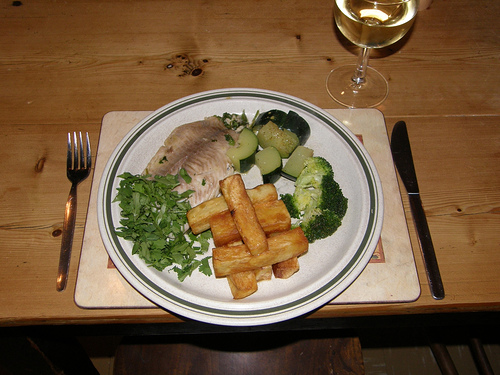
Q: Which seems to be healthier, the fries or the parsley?
A: The parsley is healthier than the fries.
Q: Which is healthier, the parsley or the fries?
A: The parsley is healthier than the fries.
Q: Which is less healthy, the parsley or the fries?
A: The fries is less healthy than the parsley.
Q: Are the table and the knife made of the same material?
A: No, the table is made of wood and the knife is made of metal.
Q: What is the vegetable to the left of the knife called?
A: The vegetable is a zucchini.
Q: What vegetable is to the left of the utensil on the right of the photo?
A: The vegetable is a zucchini.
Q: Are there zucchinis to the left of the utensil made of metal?
A: Yes, there is a zucchini to the left of the knife.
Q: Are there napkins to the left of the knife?
A: No, there is a zucchini to the left of the knife.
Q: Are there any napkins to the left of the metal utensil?
A: No, there is a zucchini to the left of the knife.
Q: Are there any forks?
A: Yes, there is a fork.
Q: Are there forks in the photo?
A: Yes, there is a fork.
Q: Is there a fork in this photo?
A: Yes, there is a fork.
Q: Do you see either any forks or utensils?
A: Yes, there is a fork.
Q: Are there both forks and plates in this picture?
A: Yes, there are both a fork and a plate.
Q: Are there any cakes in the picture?
A: No, there are no cakes.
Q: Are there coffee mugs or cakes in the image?
A: No, there are no cakes or coffee mugs.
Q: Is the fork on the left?
A: Yes, the fork is on the left of the image.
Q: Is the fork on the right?
A: No, the fork is on the left of the image.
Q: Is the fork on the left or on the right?
A: The fork is on the left of the image.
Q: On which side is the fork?
A: The fork is on the left of the image.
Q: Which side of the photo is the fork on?
A: The fork is on the left of the image.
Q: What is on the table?
A: The fork is on the table.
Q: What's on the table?
A: The fork is on the table.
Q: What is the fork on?
A: The fork is on the table.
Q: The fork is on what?
A: The fork is on the table.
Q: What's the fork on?
A: The fork is on the table.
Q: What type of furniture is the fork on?
A: The fork is on the table.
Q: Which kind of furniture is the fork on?
A: The fork is on the table.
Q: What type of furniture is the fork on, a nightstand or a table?
A: The fork is on a table.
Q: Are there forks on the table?
A: Yes, there is a fork on the table.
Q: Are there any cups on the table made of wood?
A: No, there is a fork on the table.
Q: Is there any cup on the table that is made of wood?
A: No, there is a fork on the table.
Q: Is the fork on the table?
A: Yes, the fork is on the table.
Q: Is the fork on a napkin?
A: No, the fork is on the table.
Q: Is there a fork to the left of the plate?
A: Yes, there is a fork to the left of the plate.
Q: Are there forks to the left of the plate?
A: Yes, there is a fork to the left of the plate.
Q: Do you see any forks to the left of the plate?
A: Yes, there is a fork to the left of the plate.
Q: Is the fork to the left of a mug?
A: No, the fork is to the left of the plate.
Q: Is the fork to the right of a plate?
A: No, the fork is to the left of a plate.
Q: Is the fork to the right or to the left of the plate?
A: The fork is to the left of the plate.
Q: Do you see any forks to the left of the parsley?
A: Yes, there is a fork to the left of the parsley.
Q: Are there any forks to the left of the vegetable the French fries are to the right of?
A: Yes, there is a fork to the left of the parsley.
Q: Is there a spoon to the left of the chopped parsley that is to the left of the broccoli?
A: No, there is a fork to the left of the parsley.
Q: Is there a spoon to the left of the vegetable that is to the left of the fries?
A: No, there is a fork to the left of the parsley.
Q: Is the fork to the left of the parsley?
A: Yes, the fork is to the left of the parsley.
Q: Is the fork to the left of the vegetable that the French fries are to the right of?
A: Yes, the fork is to the left of the parsley.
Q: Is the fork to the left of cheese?
A: No, the fork is to the left of the parsley.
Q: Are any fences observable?
A: No, there are no fences.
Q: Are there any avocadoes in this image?
A: No, there are no avocadoes.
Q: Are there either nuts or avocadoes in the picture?
A: No, there are no avocadoes or nuts.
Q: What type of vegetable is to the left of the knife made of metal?
A: The vegetable is a zucchini.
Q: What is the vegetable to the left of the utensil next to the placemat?
A: The vegetable is a zucchini.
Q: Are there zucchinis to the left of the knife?
A: Yes, there is a zucchini to the left of the knife.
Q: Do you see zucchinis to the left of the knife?
A: Yes, there is a zucchini to the left of the knife.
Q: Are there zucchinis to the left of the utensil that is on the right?
A: Yes, there is a zucchini to the left of the knife.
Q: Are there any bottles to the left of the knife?
A: No, there is a zucchini to the left of the knife.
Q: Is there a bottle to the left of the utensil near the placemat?
A: No, there is a zucchini to the left of the knife.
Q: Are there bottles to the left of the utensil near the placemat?
A: No, there is a zucchini to the left of the knife.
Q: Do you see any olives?
A: No, there are no olives.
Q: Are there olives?
A: No, there are no olives.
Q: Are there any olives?
A: No, there are no olives.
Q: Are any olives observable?
A: No, there are no olives.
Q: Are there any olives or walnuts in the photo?
A: No, there are no olives or walnuts.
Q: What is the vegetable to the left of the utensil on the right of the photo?
A: The vegetable is a zucchini.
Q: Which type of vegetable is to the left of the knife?
A: The vegetable is a zucchini.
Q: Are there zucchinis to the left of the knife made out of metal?
A: Yes, there is a zucchini to the left of the knife.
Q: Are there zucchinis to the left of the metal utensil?
A: Yes, there is a zucchini to the left of the knife.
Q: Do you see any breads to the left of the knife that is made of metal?
A: No, there is a zucchini to the left of the knife.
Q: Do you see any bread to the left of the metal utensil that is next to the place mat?
A: No, there is a zucchini to the left of the knife.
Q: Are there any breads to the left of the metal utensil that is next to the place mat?
A: No, there is a zucchini to the left of the knife.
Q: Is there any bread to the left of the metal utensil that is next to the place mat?
A: No, there is a zucchini to the left of the knife.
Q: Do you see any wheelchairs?
A: No, there are no wheelchairs.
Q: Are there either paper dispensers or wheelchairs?
A: No, there are no wheelchairs or paper dispensers.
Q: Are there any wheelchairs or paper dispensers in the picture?
A: No, there are no wheelchairs or paper dispensers.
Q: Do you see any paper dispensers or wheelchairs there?
A: No, there are no wheelchairs or paper dispensers.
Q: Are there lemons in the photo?
A: No, there are no lemons.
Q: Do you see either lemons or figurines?
A: No, there are no lemons or figurines.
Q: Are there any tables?
A: Yes, there is a table.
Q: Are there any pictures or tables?
A: Yes, there is a table.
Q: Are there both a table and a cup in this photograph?
A: No, there is a table but no cups.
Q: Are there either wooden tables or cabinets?
A: Yes, there is a wood table.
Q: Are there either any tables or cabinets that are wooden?
A: Yes, the table is wooden.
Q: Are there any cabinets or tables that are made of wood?
A: Yes, the table is made of wood.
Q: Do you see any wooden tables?
A: Yes, there is a wood table.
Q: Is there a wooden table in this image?
A: Yes, there is a wood table.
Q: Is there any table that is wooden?
A: Yes, there is a table that is wooden.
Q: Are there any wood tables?
A: Yes, there is a table that is made of wood.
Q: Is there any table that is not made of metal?
A: Yes, there is a table that is made of wood.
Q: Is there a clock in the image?
A: No, there are no clocks.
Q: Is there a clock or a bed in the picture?
A: No, there are no clocks or beds.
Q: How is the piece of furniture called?
A: The piece of furniture is a table.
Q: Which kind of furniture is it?
A: The piece of furniture is a table.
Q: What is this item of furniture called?
A: That is a table.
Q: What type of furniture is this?
A: That is a table.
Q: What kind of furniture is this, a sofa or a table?
A: That is a table.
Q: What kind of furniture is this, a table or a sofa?
A: That is a table.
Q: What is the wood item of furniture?
A: The piece of furniture is a table.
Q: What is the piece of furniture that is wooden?
A: The piece of furniture is a table.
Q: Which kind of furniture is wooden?
A: The furniture is a table.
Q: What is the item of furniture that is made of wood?
A: The piece of furniture is a table.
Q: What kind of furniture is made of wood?
A: The furniture is a table.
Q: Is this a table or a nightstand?
A: This is a table.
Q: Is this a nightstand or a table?
A: This is a table.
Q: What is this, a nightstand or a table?
A: This is a table.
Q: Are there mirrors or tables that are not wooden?
A: No, there is a table but it is wooden.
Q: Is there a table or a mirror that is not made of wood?
A: No, there is a table but it is made of wood.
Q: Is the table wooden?
A: Yes, the table is wooden.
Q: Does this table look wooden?
A: Yes, the table is wooden.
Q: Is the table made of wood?
A: Yes, the table is made of wood.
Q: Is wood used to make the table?
A: Yes, the table is made of wood.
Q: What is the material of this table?
A: The table is made of wood.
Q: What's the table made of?
A: The table is made of wood.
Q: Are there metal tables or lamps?
A: No, there is a table but it is wooden.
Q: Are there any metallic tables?
A: No, there is a table but it is wooden.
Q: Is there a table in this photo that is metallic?
A: No, there is a table but it is wooden.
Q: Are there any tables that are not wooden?
A: No, there is a table but it is wooden.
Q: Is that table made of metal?
A: No, the table is made of wood.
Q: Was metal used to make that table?
A: No, the table is made of wood.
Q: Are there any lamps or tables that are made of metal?
A: No, there is a table but it is made of wood.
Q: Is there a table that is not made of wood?
A: No, there is a table but it is made of wood.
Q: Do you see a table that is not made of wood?
A: No, there is a table but it is made of wood.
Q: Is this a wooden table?
A: Yes, this is a wooden table.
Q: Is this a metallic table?
A: No, this is a wooden table.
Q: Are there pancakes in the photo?
A: No, there are no pancakes.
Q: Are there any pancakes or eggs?
A: No, there are no pancakes or eggs.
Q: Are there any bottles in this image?
A: No, there are no bottles.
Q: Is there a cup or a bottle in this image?
A: No, there are no bottles or cups.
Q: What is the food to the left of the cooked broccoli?
A: The food is fries.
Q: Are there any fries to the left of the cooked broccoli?
A: Yes, there are fries to the left of the broccoli.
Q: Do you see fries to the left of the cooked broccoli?
A: Yes, there are fries to the left of the broccoli.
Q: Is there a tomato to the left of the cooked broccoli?
A: No, there are fries to the left of the broccoli.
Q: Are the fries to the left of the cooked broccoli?
A: Yes, the fries are to the left of the broccoli.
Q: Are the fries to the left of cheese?
A: No, the fries are to the left of the broccoli.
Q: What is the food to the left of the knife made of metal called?
A: The food is fries.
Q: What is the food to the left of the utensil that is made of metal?
A: The food is fries.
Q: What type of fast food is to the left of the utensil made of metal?
A: The food is fries.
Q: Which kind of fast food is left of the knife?
A: The food is fries.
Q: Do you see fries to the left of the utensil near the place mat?
A: Yes, there are fries to the left of the knife.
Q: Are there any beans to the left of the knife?
A: No, there are fries to the left of the knife.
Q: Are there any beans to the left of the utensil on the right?
A: No, there are fries to the left of the knife.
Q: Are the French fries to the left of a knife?
A: Yes, the French fries are to the left of a knife.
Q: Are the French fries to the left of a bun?
A: No, the French fries are to the left of a knife.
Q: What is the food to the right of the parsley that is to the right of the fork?
A: The food is fries.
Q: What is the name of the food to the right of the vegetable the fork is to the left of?
A: The food is fries.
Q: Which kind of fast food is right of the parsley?
A: The food is fries.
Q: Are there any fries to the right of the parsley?
A: Yes, there are fries to the right of the parsley.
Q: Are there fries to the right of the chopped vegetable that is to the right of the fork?
A: Yes, there are fries to the right of the parsley.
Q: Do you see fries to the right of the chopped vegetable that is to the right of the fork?
A: Yes, there are fries to the right of the parsley.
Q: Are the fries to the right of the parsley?
A: Yes, the fries are to the right of the parsley.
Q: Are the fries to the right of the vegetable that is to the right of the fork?
A: Yes, the fries are to the right of the parsley.